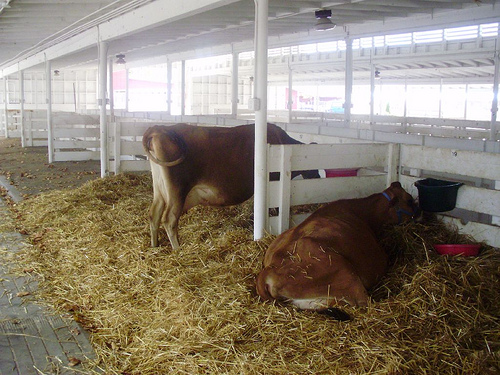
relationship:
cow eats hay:
[141, 121, 321, 252] [15, 168, 498, 372]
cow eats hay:
[253, 183, 421, 317] [15, 168, 498, 372]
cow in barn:
[141, 121, 321, 252] [2, 4, 494, 372]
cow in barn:
[253, 183, 421, 317] [2, 4, 494, 372]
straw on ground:
[123, 260, 258, 354] [1, 145, 495, 369]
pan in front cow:
[431, 225, 476, 267] [272, 172, 426, 324]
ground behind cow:
[1, 145, 495, 369] [141, 121, 321, 252]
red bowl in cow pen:
[439, 231, 486, 262] [0, 5, 496, 370]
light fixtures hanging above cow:
[311, 9, 333, 31] [253, 183, 421, 317]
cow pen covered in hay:
[0, 5, 496, 370] [45, 183, 493, 364]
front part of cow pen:
[5, 177, 495, 370] [0, 5, 496, 370]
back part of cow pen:
[2, 107, 142, 201] [0, 5, 496, 370]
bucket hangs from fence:
[414, 175, 463, 220] [264, 140, 499, 252]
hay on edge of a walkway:
[15, 168, 498, 372] [1, 183, 116, 373]